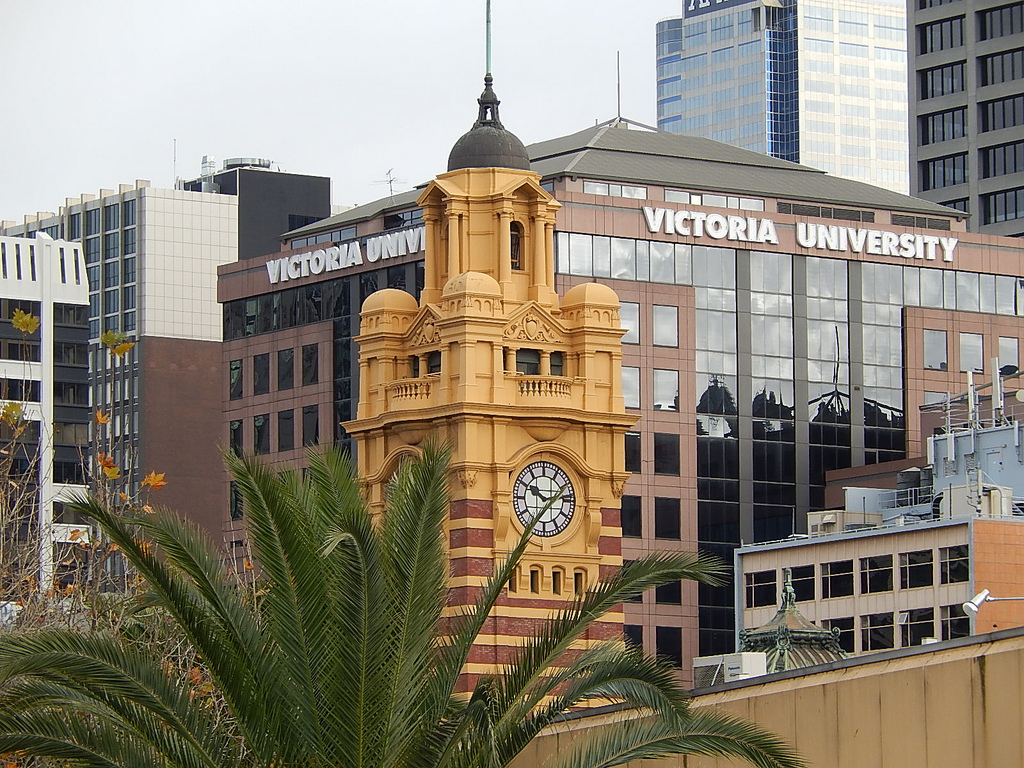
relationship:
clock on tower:
[498, 454, 578, 554] [343, 46, 626, 702]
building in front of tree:
[563, 178, 1019, 567] [1, 451, 769, 766]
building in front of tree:
[358, 74, 633, 698] [1, 451, 769, 766]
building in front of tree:
[531, 656, 1022, 765] [1, 451, 769, 766]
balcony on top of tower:
[516, 374, 577, 400] [361, 0, 624, 716]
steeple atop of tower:
[437, 3, 537, 168] [361, 0, 624, 716]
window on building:
[753, 253, 792, 291] [562, 178, 1017, 567]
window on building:
[756, 383, 813, 437] [562, 178, 1017, 567]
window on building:
[754, 446, 796, 538] [562, 178, 1017, 567]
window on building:
[756, 484, 795, 538] [562, 178, 1017, 567]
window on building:
[694, 415, 736, 479] [562, 178, 1017, 567]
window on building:
[659, 501, 682, 541] [562, 178, 1017, 567]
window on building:
[652, 432, 682, 477] [562, 178, 1017, 567]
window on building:
[653, 371, 679, 410] [562, 178, 1017, 567]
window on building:
[662, 308, 679, 353] [562, 178, 1017, 567]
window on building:
[611, 239, 633, 281] [562, 178, 1017, 567]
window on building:
[571, 229, 597, 277] [562, 178, 1017, 567]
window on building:
[595, 237, 615, 279] [562, 178, 1017, 567]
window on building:
[706, 500, 739, 548] [562, 178, 1017, 567]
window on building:
[611, 238, 634, 276] [562, 178, 1017, 567]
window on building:
[754, 418, 799, 482] [562, 178, 1017, 567]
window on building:
[647, 242, 670, 278] [562, 178, 1017, 567]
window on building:
[663, 240, 686, 283] [562, 178, 1017, 567]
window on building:
[699, 242, 745, 282] [562, 178, 1017, 567]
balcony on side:
[517, 375, 578, 401] [464, 0, 636, 716]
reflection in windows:
[630, 364, 914, 643] [655, 264, 913, 591]